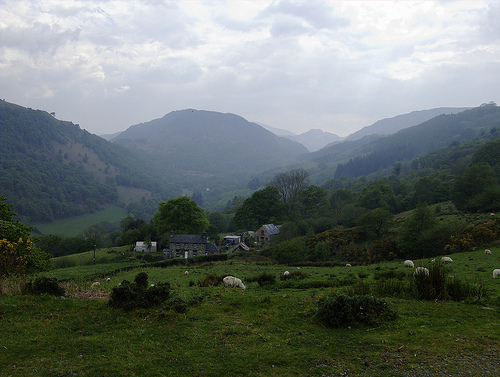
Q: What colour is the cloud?
A: White.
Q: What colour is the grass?
A: Green.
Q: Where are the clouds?
A: In the sky.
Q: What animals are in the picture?
A: Sheep.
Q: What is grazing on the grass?
A: Sheep.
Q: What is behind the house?
A: Trees.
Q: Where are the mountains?
A: Behind the sheep.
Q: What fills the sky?
A: Clouds.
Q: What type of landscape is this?
A: Mountainous.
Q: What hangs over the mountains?
A: Fog.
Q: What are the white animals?
A: Sheep.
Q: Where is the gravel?
A: Bottom right corner of picture.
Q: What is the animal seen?
A: Sheep.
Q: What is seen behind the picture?
A: Mountain.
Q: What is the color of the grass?
A: Green.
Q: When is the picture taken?
A: Daytime.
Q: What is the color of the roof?
A: Black.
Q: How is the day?
A: Cloudy.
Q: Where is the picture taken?
A: On a farm.